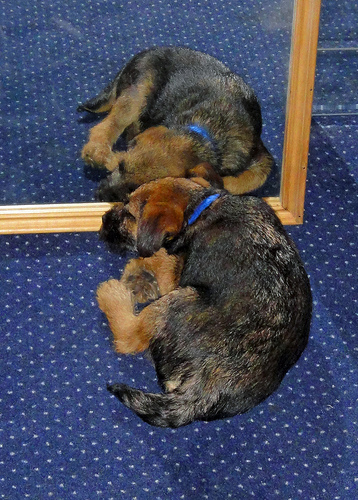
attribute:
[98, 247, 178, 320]
paws — brown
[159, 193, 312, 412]
fur —  shiny sheen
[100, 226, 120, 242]
mouth —  black 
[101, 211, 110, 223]
nose —  black 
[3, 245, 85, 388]
carpet —  blue and white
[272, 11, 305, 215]
frame —  brown,   mirror's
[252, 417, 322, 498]
floor — carpeted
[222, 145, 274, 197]
skin —  round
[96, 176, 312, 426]
dog — brown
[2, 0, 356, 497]
carpeting —  royal-blue,  with white dots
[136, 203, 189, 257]
ear — fuzzy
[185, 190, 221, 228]
collar —  bright blue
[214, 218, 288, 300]
fur —  black 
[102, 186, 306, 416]
dog — small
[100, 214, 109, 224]
nose —  black 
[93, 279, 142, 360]
leg — brown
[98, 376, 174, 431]
tail —  short,  lifted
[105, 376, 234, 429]
tail —  black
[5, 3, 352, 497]
floor — carpeted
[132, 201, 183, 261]
ears —  brown and black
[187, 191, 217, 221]
collar — blue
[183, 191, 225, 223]
collar —  blue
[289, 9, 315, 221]
frame —  raised,  wood